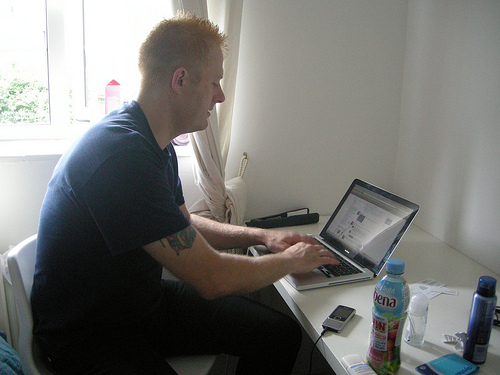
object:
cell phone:
[321, 301, 355, 334]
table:
[239, 213, 498, 375]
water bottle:
[367, 256, 411, 374]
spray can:
[460, 275, 497, 365]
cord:
[306, 326, 328, 375]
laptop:
[269, 177, 420, 292]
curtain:
[169, 0, 252, 228]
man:
[30, 10, 340, 373]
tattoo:
[158, 226, 196, 258]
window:
[0, 0, 192, 150]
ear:
[168, 66, 189, 97]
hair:
[137, 14, 229, 73]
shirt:
[29, 101, 192, 336]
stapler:
[248, 205, 320, 227]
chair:
[5, 231, 220, 375]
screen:
[317, 179, 419, 277]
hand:
[284, 242, 343, 274]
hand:
[262, 230, 319, 254]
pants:
[28, 278, 303, 375]